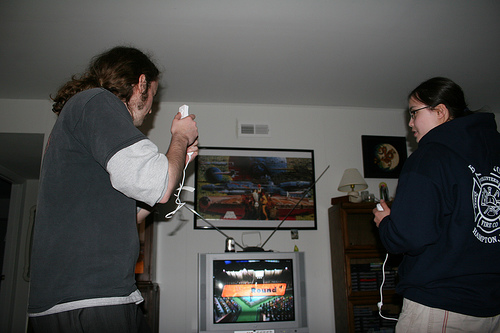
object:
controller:
[178, 104, 188, 119]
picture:
[193, 145, 317, 230]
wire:
[165, 155, 192, 219]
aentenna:
[261, 164, 331, 248]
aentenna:
[184, 205, 245, 249]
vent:
[238, 123, 272, 136]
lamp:
[337, 168, 369, 203]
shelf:
[341, 202, 376, 209]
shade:
[338, 168, 368, 192]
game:
[213, 259, 295, 324]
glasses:
[409, 105, 431, 118]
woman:
[370, 76, 500, 332]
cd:
[371, 262, 384, 267]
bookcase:
[326, 195, 402, 333]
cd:
[371, 268, 382, 269]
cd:
[360, 279, 377, 282]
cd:
[360, 272, 376, 275]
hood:
[417, 112, 499, 174]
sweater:
[377, 113, 500, 320]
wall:
[280, 104, 355, 139]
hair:
[49, 40, 167, 116]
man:
[25, 46, 199, 333]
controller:
[376, 203, 384, 212]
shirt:
[27, 87, 169, 313]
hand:
[170, 112, 198, 146]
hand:
[372, 199, 391, 227]